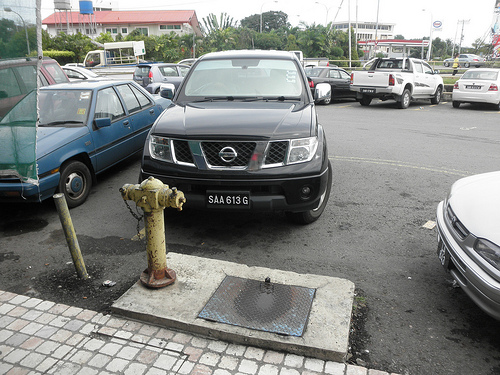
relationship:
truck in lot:
[350, 58, 444, 109] [346, 114, 496, 156]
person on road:
[447, 51, 464, 75] [315, 92, 499, 172]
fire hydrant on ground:
[119, 176, 186, 287] [179, 222, 385, 288]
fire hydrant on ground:
[119, 176, 186, 287] [125, 257, 217, 304]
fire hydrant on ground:
[119, 176, 186, 287] [3, 101, 498, 373]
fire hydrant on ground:
[114, 172, 195, 292] [88, 238, 138, 313]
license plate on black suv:
[206, 191, 252, 208] [138, 51, 333, 223]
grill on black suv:
[149, 137, 318, 172] [138, 51, 333, 223]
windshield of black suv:
[185, 56, 305, 101] [138, 51, 333, 223]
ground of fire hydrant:
[0, 98, 500, 375] [119, 176, 186, 287]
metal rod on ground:
[52, 193, 91, 280] [0, 98, 500, 375]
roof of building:
[42, 9, 199, 26] [37, 7, 204, 50]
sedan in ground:
[448, 65, 498, 110] [0, 98, 500, 375]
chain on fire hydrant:
[123, 179, 163, 249] [119, 176, 186, 287]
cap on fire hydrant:
[169, 187, 188, 209] [119, 176, 186, 287]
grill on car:
[164, 120, 324, 194] [148, 52, 345, 257]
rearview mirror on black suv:
[314, 83, 331, 105] [138, 51, 333, 223]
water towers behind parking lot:
[52, 1, 101, 32] [0, 46, 499, 373]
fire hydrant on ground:
[119, 176, 186, 287] [6, 236, 480, 372]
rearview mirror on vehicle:
[311, 80, 334, 103] [134, 40, 336, 231]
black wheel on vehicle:
[51, 155, 85, 200] [3, 73, 173, 206]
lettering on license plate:
[206, 193, 249, 205] [199, 186, 265, 214]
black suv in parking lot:
[129, 37, 333, 234] [0, 46, 499, 373]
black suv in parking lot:
[138, 51, 333, 223] [0, 40, 498, 267]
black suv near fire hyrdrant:
[138, 51, 333, 223] [116, 172, 187, 291]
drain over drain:
[196, 275, 315, 336] [191, 249, 368, 363]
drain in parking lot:
[191, 249, 368, 363] [0, 46, 499, 373]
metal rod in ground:
[52, 193, 91, 280] [0, 98, 500, 375]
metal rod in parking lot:
[48, 188, 92, 273] [0, 46, 499, 373]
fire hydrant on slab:
[119, 176, 186, 287] [103, 244, 361, 360]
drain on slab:
[196, 275, 315, 336] [103, 244, 361, 360]